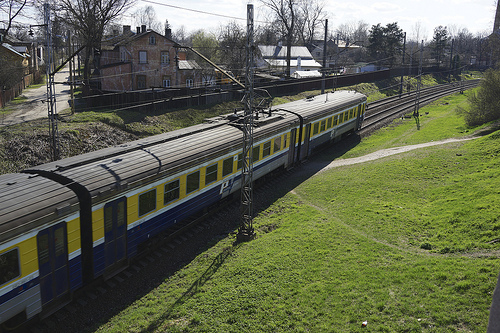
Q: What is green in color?
A: The grass.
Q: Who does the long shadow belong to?
A: The train.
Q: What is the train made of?
A: Metal.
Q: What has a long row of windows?
A: The train.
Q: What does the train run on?
A: Tracks.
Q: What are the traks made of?
A: Metal.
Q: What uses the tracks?
A: Trains.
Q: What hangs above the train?
A: Cable lines.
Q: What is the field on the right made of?
A: Grass.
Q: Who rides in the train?
A: Passangers.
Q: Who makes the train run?
A: The train operator.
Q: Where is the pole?
A: Grass.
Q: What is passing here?
A: Train.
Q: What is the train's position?
A: In motion.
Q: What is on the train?
A: Windows.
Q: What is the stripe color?
A: Yellow.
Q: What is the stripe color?
A: Blue.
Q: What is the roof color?
A: Gray.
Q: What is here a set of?
A: Tracks.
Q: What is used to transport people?
A: The train.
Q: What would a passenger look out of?
A: The window.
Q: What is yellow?
A: The stripe along the sides of the train's windows.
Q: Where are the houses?
A: To the left of the train.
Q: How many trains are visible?
A: One.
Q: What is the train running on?
A: Railroad tracks.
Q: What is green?
A: The grass.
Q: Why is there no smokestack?
A: The train is electric.